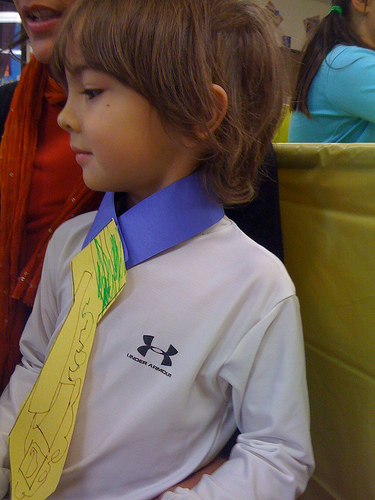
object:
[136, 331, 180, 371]
logo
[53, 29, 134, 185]
face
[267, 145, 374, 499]
wall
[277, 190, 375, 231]
lines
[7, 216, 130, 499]
tie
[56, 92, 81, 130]
nose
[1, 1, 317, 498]
boy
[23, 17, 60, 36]
lips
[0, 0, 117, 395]
woman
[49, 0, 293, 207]
hair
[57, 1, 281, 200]
head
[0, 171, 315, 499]
shirt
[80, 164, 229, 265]
blue collar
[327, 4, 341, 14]
ponytail holder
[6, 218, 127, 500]
paper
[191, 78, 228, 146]
ear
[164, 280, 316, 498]
arm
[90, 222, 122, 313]
drawing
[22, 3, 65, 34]
mouth